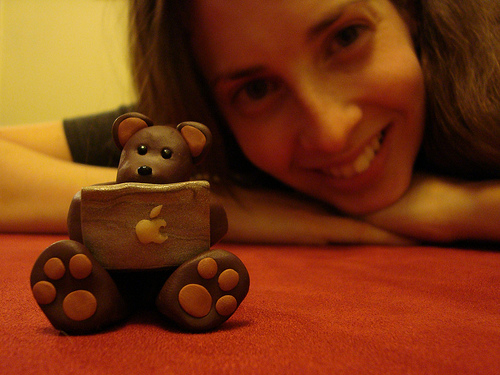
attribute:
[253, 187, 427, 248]
hands — both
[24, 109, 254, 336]
teddy bear — ceramic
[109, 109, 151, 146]
ceramic ear — small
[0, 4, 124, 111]
wall — yellow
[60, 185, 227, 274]
cover — top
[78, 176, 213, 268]
tablet — brown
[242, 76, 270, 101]
left eye — black, little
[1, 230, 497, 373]
fabric — fuzzy, red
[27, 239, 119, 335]
feet — mouse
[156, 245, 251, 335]
feet — mouse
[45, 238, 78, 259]
big feet — bear's, tip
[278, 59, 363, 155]
nose — big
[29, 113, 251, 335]
bear figurine — small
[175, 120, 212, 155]
ear — small, ceramic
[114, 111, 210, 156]
ears — pink, bordered in brown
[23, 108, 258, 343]
bear — little, ceramic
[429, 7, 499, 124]
hair — dry, brown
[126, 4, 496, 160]
hair — large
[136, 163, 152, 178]
black nose — upturned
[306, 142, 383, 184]
teeth — white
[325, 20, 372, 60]
eye — little, black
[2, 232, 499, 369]
red surface — smooth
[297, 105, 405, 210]
mouth — big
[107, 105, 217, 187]
head — brown, bear's, top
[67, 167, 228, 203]
edge — wavy